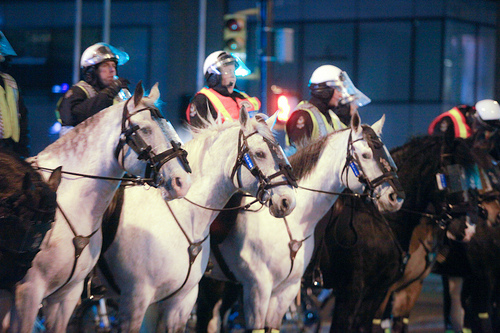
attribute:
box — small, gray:
[264, 24, 317, 77]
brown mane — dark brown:
[278, 125, 348, 185]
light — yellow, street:
[218, 10, 260, 82]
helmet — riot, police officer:
[78, 40, 129, 68]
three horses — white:
[7, 97, 412, 331]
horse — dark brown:
[193, 120, 483, 330]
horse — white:
[198, 107, 404, 331]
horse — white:
[1, 80, 196, 332]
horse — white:
[95, 119, 281, 312]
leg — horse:
[242, 283, 274, 331]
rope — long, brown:
[184, 197, 259, 212]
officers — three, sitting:
[65, 40, 375, 138]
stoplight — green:
[220, 11, 243, 52]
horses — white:
[17, 86, 192, 330]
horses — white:
[132, 92, 295, 330]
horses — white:
[248, 115, 410, 331]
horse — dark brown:
[188, 102, 435, 325]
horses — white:
[0, 78, 492, 329]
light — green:
[224, 17, 241, 74]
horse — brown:
[10, 149, 74, 303]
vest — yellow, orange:
[181, 87, 268, 128]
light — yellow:
[217, 11, 259, 76]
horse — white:
[188, 137, 300, 234]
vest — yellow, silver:
[298, 99, 361, 145]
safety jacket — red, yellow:
[428, 96, 470, 141]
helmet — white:
[75, 40, 121, 66]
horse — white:
[15, 107, 202, 249]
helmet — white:
[312, 63, 338, 93]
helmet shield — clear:
[340, 69, 371, 112]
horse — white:
[78, 103, 296, 330]